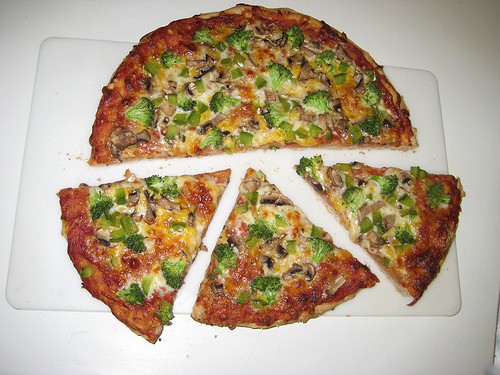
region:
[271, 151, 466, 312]
a slice of pizza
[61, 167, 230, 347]
a slice of pizza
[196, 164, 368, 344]
a slice of pizza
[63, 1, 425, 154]
a slice of pizza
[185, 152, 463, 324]
two slices of pizza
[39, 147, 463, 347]
three slices of pizza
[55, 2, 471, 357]
a pizza cut into slices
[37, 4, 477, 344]
a picture of a delicious picture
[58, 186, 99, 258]
crunchy part of pizza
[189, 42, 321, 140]
pizza toppings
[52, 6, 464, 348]
four uneven pieces of pizza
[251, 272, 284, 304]
veggie pizza with broccoli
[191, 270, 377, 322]
red pizza sauce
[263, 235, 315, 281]
mushrooms on pizza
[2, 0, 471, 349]
pizza on white cutting board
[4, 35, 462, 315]
cutting board too small for pizza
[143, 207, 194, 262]
pizza has yellow orange cheese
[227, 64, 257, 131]
cheese bubbles are caramelized on top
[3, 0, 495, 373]
table is white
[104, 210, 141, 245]
bell peppers on pizza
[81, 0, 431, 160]
HALF OF A PIZZA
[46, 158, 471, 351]
THREE SLICES OF PIZZA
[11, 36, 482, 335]
A CLEAR CUTTING BOARD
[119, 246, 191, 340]
BROCCOLI ON A SLICE OF PIZZA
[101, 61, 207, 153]
BROCCOLI AND MUSHROOMS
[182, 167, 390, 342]
THIN CRUST SLICE OF VEGGIE PIZZA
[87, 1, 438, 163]
A HALF OF VEGGIE PIZZA ON A CLEAR CUTTING BOARD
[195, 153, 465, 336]
TWO SLICES OF PIZZA WITH MUSHROOMS, CHEESE AND BROCCOLI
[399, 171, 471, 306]
A WELL DONE PIECE OF CRUST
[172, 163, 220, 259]
WELL DONE CHEESE ON A SLICE OF PIZZA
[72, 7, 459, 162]
half of a vegetable pizza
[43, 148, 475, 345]
three slices of pizza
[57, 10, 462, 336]
a pizza that's partially cut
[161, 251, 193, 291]
a small piece of broccoli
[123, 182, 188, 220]
thinly sliced mushrooms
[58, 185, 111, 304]
red sauce on crust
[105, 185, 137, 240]
diced green peppers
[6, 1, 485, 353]
a white rectangular cutting board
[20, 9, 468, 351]
a vegetarian lunch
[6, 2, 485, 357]
a white table cloth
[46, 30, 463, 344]
a pizza place on a cutting board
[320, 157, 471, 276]
a triangular slice of pizza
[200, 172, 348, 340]
a triangular slice of pizza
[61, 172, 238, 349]
a triangular slice of pizza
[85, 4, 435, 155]
top half of pizza has yet to be sliced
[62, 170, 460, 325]
bottom half of pizza is sliced into three pieces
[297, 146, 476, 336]
pizza has broccoli topping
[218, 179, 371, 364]
pizza has mushroom topping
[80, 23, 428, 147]
cheese on the pizza is nicely charred and blistered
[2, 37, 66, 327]
white cutting board beneath the pizza